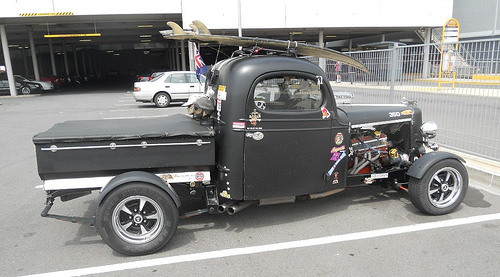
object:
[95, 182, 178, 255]
wheel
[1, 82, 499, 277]
pavement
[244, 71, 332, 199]
door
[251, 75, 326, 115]
window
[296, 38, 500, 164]
rail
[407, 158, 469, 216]
wheel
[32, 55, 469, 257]
truck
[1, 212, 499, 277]
line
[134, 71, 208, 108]
car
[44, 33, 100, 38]
bar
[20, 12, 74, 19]
warning bar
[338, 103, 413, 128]
hood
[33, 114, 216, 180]
bed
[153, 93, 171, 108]
wheel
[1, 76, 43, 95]
car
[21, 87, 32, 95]
wheel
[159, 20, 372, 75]
surfboard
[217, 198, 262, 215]
muffler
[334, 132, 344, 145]
sticker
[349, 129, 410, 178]
engine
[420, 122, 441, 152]
headlight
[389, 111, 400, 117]
number